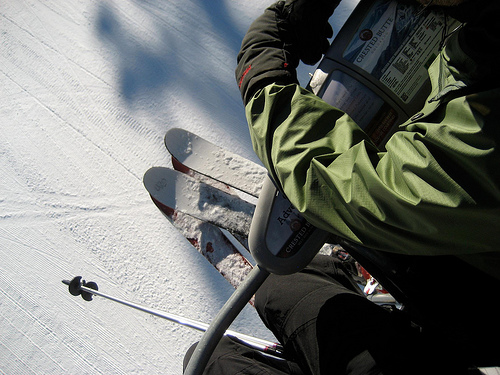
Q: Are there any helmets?
A: No, there are no helmets.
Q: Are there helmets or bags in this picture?
A: No, there are no helmets or bags.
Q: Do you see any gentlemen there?
A: No, there are no gentlemen.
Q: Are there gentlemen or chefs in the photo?
A: No, there are no gentlemen or chefs.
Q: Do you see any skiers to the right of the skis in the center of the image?
A: Yes, there is a skier to the right of the skis.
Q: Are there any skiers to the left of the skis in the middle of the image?
A: No, the skier is to the right of the skis.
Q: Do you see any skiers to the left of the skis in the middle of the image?
A: No, the skier is to the right of the skis.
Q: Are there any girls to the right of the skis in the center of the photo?
A: No, there is a skier to the right of the skis.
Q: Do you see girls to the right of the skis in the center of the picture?
A: No, there is a skier to the right of the skis.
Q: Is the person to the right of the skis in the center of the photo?
A: Yes, the skier is to the right of the skis.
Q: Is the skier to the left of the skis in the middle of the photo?
A: No, the skier is to the right of the skis.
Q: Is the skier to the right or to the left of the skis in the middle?
A: The skier is to the right of the skis.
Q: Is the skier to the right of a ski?
A: Yes, the skier is to the right of a ski.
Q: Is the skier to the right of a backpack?
A: No, the skier is to the right of a ski.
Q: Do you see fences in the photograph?
A: No, there are no fences.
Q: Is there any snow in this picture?
A: Yes, there is snow.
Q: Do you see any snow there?
A: Yes, there is snow.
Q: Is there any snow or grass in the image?
A: Yes, there is snow.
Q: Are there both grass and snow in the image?
A: No, there is snow but no grass.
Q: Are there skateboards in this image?
A: No, there are no skateboards.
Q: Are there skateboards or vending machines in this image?
A: No, there are no skateboards or vending machines.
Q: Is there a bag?
A: No, there are no bags.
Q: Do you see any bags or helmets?
A: No, there are no bags or helmets.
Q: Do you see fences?
A: No, there are no fences.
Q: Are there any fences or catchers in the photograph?
A: No, there are no fences or catchers.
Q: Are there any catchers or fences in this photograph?
A: No, there are no fences or catchers.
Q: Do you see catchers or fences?
A: No, there are no fences or catchers.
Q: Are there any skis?
A: Yes, there are skis.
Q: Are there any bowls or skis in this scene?
A: Yes, there are skis.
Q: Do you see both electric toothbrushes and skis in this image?
A: No, there are skis but no electric toothbrushes.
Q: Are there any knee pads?
A: No, there are no knee pads.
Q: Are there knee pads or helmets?
A: No, there are no knee pads or helmets.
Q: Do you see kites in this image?
A: No, there are no kites.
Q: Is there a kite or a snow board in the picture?
A: No, there are no kites or snowboards.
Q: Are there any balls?
A: No, there are no balls.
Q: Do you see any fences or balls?
A: No, there are no balls or fences.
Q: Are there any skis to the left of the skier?
A: Yes, there is a ski to the left of the skier.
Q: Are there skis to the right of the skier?
A: No, the ski is to the left of the skier.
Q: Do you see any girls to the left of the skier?
A: No, there is a ski to the left of the skier.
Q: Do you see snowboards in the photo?
A: No, there are no snowboards.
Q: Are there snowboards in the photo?
A: No, there are no snowboards.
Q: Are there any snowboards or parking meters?
A: No, there are no snowboards or parking meters.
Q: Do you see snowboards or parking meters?
A: No, there are no snowboards or parking meters.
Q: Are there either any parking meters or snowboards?
A: No, there are no snowboards or parking meters.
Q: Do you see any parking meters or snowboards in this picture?
A: No, there are no snowboards or parking meters.